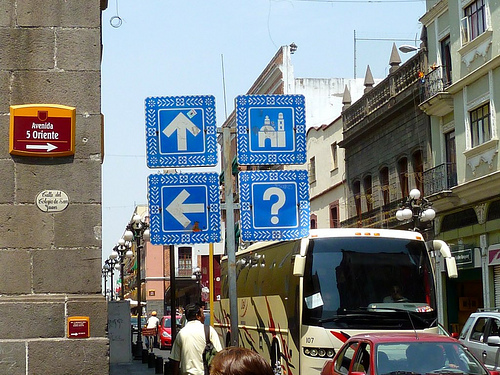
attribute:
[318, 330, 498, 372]
car — red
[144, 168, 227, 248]
sign — blue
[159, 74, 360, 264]
blue signs — blue 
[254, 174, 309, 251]
mark — question mark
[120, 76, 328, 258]
signs — blue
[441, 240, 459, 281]
view mirror — rear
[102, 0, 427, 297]
sky — blue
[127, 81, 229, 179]
sign — Blue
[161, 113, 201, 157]
arrow — up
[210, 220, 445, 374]
bus — large , white 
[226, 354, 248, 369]
hair — brown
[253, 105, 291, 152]
church — small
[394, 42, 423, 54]
security camera — small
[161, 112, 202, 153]
arrow — white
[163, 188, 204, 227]
arrow — white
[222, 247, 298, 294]
windows — side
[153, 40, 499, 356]
building — gray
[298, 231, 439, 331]
window — large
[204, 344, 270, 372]
hair — brown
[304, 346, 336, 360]
headlight — off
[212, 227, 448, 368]
tour bus — white 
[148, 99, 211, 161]
arrow — up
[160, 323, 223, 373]
shirt — white 